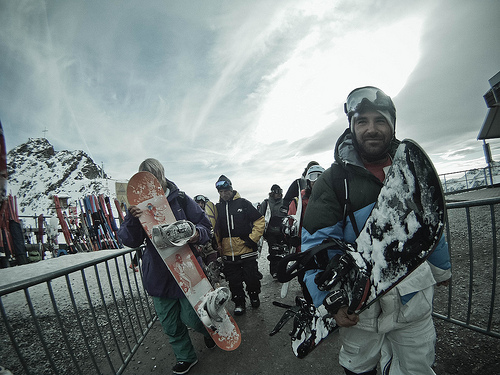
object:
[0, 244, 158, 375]
fence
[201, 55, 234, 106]
breaks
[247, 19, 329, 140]
clouds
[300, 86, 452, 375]
man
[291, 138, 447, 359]
snowboard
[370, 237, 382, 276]
snow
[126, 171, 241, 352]
snowboard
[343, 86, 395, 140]
snowhat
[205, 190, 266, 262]
jacket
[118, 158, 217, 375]
people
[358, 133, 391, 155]
beard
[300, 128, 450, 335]
blue & black jacket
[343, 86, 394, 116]
goggles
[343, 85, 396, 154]
head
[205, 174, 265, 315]
man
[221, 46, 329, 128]
sky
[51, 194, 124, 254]
skis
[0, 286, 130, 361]
rails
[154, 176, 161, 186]
face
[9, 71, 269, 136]
skies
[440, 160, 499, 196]
mountain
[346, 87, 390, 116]
pair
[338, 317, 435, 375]
pants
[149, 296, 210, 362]
pants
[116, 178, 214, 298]
jacket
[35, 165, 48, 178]
snow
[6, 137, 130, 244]
hill